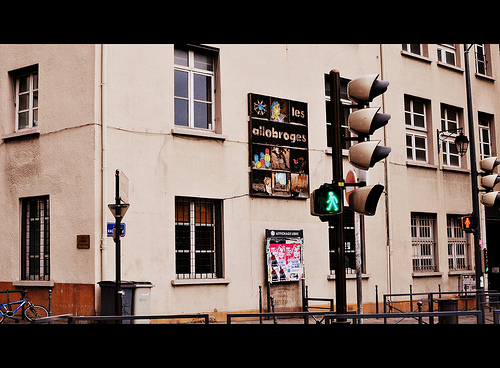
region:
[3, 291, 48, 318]
a blue bicycle leaning against a rail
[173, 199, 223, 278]
Caging over a set of windows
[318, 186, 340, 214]
A green "walk" pedestrian light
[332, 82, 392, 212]
A set of traffic lights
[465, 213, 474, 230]
A orange "caution" walking light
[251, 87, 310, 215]
A sign hanging on the side of a building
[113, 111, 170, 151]
Wiring going from window to window on the building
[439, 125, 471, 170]
A street light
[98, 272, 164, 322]
a trash bin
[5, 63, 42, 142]
A set of windows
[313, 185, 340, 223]
green pedestrian walk light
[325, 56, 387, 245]
traffic lights on pole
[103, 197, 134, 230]
rear of triangular sign on pole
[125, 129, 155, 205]
outside of building is brown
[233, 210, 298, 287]
red and white sign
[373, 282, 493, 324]
black rails near building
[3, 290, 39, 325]
blue bike under window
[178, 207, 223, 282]
white frame on window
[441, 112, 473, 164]
black street light on pole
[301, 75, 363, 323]
street lights on black pole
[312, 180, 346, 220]
Lighted green traffic sign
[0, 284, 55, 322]
Blue bicycle leaning against wall of building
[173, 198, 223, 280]
Black metal bars on window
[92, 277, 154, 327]
Two trash bins next to building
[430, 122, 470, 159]
Black lantern attached to wall of building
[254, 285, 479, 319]
Black metal poles on city sidewalk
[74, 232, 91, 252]
Gold and black plaque on side of building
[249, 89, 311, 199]
Colorful sign on side of building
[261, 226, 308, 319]
Red and white poster on sidewalk billboard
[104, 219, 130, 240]
Blue and white sign on side of corner building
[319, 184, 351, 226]
green sign for pedestrians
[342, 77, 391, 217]
gold bordered traffic lights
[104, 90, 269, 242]
building has tan exterior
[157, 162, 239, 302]
white border on window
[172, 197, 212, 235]
brown blinds in window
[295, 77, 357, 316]
traffic light on black pole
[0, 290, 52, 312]
blue bike under window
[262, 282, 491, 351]
black rail under traffic lights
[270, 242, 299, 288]
red and white poster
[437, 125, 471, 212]
black street light on pole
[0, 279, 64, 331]
blue bicycle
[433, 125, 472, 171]
elegant street light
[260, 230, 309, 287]
community board of events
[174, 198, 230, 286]
rod iron window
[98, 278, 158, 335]
2 trach bins black and white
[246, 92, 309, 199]
wonderful art display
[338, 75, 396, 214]
stop light with four lights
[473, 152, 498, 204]
stop light with three lights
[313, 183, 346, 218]
green pedistrian sign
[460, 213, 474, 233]
red pedistrian sign on the light pole